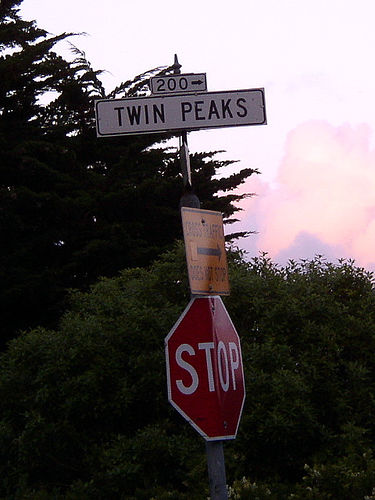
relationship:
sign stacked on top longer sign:
[96, 87, 265, 138] [91, 87, 266, 139]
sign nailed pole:
[152, 289, 272, 442] [179, 136, 226, 498]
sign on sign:
[96, 87, 265, 138] [96, 87, 265, 138]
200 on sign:
[153, 78, 192, 91] [96, 87, 265, 138]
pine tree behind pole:
[0, 0, 258, 340] [175, 99, 228, 497]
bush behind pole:
[247, 262, 366, 495] [169, 53, 230, 498]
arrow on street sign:
[189, 76, 206, 87] [148, 72, 208, 95]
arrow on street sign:
[192, 79, 203, 84] [148, 72, 208, 95]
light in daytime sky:
[267, 177, 374, 262] [44, 1, 373, 267]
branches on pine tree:
[2, 44, 147, 97] [0, 5, 248, 333]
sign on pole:
[91, 71, 268, 139] [169, 53, 228, 500]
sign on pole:
[178, 204, 231, 296] [169, 53, 228, 500]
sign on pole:
[152, 289, 272, 442] [169, 53, 228, 500]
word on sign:
[112, 102, 169, 126] [94, 85, 267, 138]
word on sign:
[179, 96, 249, 120] [94, 85, 267, 138]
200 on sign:
[157, 76, 188, 92] [148, 71, 207, 94]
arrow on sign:
[196, 241, 220, 261] [178, 204, 231, 296]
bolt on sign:
[199, 214, 206, 224] [178, 204, 231, 296]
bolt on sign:
[205, 284, 213, 292] [178, 204, 231, 296]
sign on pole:
[94, 85, 267, 138] [169, 53, 230, 498]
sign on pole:
[150, 71, 207, 96] [169, 53, 230, 498]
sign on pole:
[180, 205, 230, 297] [203, 445, 238, 494]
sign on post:
[97, 61, 272, 443] [204, 449, 241, 491]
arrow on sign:
[198, 244, 222, 262] [183, 197, 232, 301]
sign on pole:
[150, 71, 206, 94] [202, 435, 229, 493]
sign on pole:
[152, 289, 272, 442] [198, 440, 229, 498]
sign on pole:
[152, 289, 272, 442] [198, 438, 233, 497]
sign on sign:
[96, 87, 265, 138] [89, 84, 273, 146]